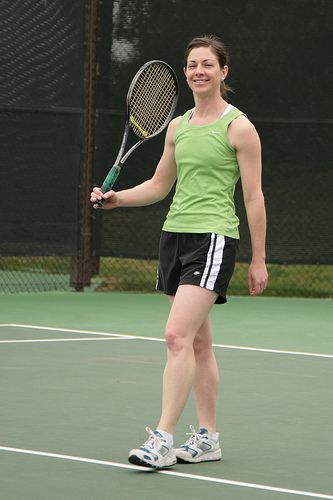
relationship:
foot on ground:
[136, 439, 169, 466] [1, 266, 330, 497]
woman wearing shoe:
[90, 35, 269, 468] [127, 425, 176, 467]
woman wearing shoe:
[90, 35, 269, 468] [173, 427, 221, 462]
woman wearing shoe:
[90, 35, 269, 468] [127, 429, 178, 470]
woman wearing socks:
[90, 35, 269, 468] [204, 429, 219, 439]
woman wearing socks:
[90, 35, 269, 468] [155, 428, 173, 445]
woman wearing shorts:
[90, 35, 269, 468] [154, 229, 240, 306]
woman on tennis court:
[90, 35, 269, 468] [1, 291, 333, 500]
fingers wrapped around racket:
[89, 186, 115, 209] [70, 55, 188, 220]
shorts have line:
[183, 234, 237, 303] [198, 232, 226, 290]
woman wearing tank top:
[90, 35, 269, 468] [158, 102, 246, 239]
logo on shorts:
[192, 270, 200, 275] [153, 229, 237, 303]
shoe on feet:
[172, 426, 226, 462] [124, 421, 225, 468]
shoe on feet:
[127, 430, 181, 466] [124, 421, 225, 468]